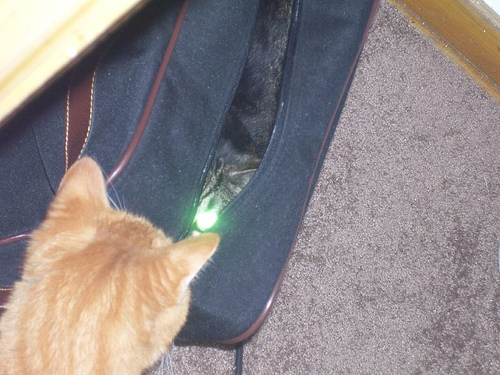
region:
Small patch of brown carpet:
[267, 326, 292, 366]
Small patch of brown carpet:
[276, 276, 338, 340]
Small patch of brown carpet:
[293, 218, 340, 278]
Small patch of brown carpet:
[315, 158, 361, 237]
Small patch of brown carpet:
[322, 126, 381, 168]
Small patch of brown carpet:
[345, 85, 384, 117]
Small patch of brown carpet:
[355, 58, 410, 100]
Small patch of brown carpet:
[374, 16, 444, 80]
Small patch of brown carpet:
[424, 59, 471, 166]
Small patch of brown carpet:
[385, 131, 440, 225]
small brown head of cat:
[4, 163, 239, 373]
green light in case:
[185, 193, 230, 230]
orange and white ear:
[158, 233, 223, 284]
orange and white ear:
[58, 155, 112, 209]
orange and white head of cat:
[12, 172, 174, 373]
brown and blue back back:
[85, 16, 207, 147]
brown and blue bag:
[247, 33, 385, 158]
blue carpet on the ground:
[290, 108, 454, 310]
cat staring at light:
[0, 136, 267, 347]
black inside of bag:
[220, 59, 274, 159]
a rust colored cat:
[6, 156, 219, 373]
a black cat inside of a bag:
[195, 1, 301, 231]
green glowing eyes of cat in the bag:
[194, 202, 219, 232]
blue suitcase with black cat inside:
[10, 4, 372, 344]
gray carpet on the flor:
[157, 0, 497, 374]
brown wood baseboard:
[393, 2, 498, 97]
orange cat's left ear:
[57, 166, 106, 218]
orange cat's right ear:
[169, 238, 216, 281]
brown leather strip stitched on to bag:
[66, 74, 91, 171]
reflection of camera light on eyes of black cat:
[194, 208, 217, 231]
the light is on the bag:
[192, 192, 219, 238]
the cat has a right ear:
[52, 142, 107, 217]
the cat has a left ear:
[152, 220, 222, 295]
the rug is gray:
[391, 184, 448, 299]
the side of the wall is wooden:
[445, 13, 498, 62]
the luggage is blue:
[113, 8, 340, 168]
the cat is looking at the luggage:
[32, 156, 217, 371]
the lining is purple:
[139, 75, 166, 107]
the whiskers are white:
[151, 357, 193, 370]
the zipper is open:
[232, 71, 291, 127]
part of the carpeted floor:
[461, 346, 498, 373]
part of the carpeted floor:
[416, 343, 449, 371]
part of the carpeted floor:
[336, 339, 378, 374]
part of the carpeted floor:
[272, 330, 315, 373]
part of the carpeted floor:
[307, 261, 347, 310]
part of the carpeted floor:
[357, 248, 409, 286]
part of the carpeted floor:
[425, 226, 472, 275]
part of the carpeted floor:
[438, 155, 480, 207]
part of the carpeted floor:
[368, 152, 401, 212]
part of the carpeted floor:
[385, 88, 419, 133]